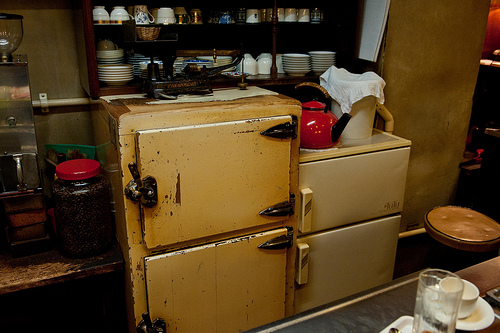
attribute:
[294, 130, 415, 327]
fridge — small, white, tan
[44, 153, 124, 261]
jar — red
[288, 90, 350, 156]
teapot — red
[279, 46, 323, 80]
plates — white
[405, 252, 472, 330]
glass — empty, clear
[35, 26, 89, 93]
wall — brown, gray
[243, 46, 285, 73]
bowels — white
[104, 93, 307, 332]
refrigerator — yellow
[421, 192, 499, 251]
seat — brown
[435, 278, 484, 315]
cup — white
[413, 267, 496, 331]
saucer — white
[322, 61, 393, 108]
dishcloth — white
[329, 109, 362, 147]
spout — black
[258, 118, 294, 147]
hinge — black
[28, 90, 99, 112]
pipe — white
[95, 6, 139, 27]
coffe cup — gold